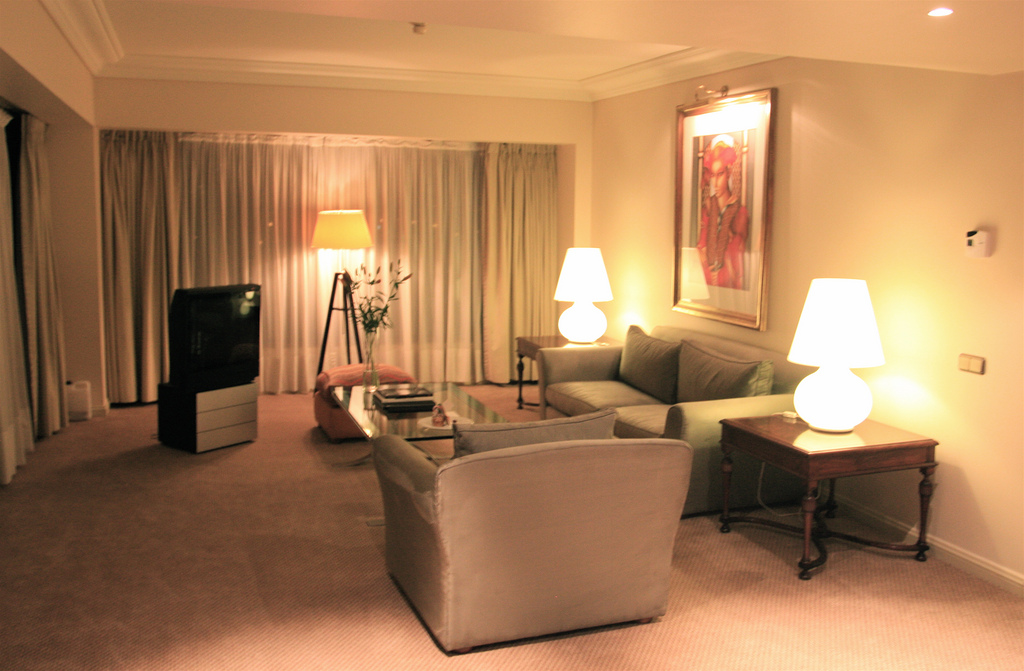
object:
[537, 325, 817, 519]
sofa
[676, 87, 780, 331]
picture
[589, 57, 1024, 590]
wall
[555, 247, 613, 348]
light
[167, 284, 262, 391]
tv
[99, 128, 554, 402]
curtains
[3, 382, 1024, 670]
floor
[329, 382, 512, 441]
table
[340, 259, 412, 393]
flowers